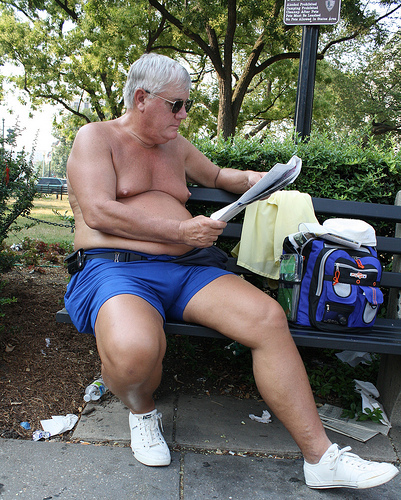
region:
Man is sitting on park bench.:
[62, 51, 399, 488]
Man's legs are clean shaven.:
[95, 272, 343, 457]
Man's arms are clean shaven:
[72, 129, 272, 245]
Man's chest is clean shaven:
[65, 115, 213, 257]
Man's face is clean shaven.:
[132, 83, 197, 150]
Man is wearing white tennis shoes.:
[126, 403, 399, 495]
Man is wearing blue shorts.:
[65, 244, 245, 340]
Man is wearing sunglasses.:
[132, 83, 197, 117]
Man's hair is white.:
[111, 46, 196, 117]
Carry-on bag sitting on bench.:
[272, 214, 390, 340]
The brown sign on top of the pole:
[279, 0, 342, 26]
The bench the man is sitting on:
[52, 182, 400, 418]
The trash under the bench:
[15, 345, 389, 442]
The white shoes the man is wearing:
[125, 406, 398, 490]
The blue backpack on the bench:
[278, 231, 385, 335]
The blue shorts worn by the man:
[59, 248, 233, 333]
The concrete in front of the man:
[1, 384, 399, 498]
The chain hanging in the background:
[8, 205, 73, 234]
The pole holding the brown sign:
[294, 22, 321, 144]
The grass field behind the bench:
[4, 188, 81, 251]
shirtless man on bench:
[60, 45, 349, 446]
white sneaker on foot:
[296, 441, 399, 490]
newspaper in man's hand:
[199, 148, 309, 240]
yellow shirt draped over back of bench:
[223, 187, 327, 284]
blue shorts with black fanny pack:
[48, 244, 242, 335]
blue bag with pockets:
[304, 248, 384, 335]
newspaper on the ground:
[310, 400, 391, 446]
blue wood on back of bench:
[327, 197, 391, 218]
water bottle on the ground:
[79, 370, 108, 408]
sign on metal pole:
[274, 1, 362, 41]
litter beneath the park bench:
[287, 347, 394, 444]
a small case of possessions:
[268, 215, 386, 331]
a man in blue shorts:
[60, 50, 397, 487]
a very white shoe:
[122, 403, 174, 470]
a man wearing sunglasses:
[113, 53, 198, 139]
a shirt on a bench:
[233, 186, 320, 283]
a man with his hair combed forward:
[113, 50, 194, 143]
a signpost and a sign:
[272, 0, 350, 178]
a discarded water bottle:
[76, 372, 110, 410]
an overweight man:
[43, 69, 378, 495]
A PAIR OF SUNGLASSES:
[145, 91, 204, 116]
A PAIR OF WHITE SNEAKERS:
[125, 409, 399, 494]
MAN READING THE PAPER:
[45, 50, 350, 371]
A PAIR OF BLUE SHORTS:
[61, 251, 241, 335]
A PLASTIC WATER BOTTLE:
[73, 373, 110, 404]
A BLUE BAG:
[276, 226, 388, 333]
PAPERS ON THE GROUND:
[312, 372, 395, 444]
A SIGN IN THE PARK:
[270, 0, 344, 143]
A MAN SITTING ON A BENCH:
[28, 47, 384, 373]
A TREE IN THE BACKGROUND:
[141, 3, 291, 160]